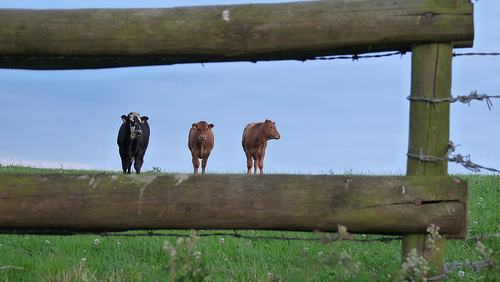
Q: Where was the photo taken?
A: It was taken at the field.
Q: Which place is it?
A: It is a field.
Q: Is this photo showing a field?
A: Yes, it is showing a field.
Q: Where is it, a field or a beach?
A: It is a field.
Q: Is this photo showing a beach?
A: No, the picture is showing a field.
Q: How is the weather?
A: It is clear.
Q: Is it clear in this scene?
A: Yes, it is clear.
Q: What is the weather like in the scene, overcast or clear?
A: It is clear.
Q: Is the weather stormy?
A: No, it is clear.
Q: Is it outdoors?
A: Yes, it is outdoors.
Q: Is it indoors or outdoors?
A: It is outdoors.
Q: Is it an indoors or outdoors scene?
A: It is outdoors.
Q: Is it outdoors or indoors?
A: It is outdoors.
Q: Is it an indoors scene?
A: No, it is outdoors.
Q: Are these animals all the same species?
A: Yes, all the animals are cows.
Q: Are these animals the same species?
A: Yes, all the animals are cows.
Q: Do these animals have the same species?
A: Yes, all the animals are cows.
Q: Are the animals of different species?
A: No, all the animals are cows.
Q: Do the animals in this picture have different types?
A: No, all the animals are cows.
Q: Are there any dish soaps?
A: No, there are no dish soaps.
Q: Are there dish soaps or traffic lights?
A: No, there are no dish soaps or traffic lights.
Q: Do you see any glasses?
A: No, there are no glasses.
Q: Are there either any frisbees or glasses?
A: No, there are no glasses or frisbees.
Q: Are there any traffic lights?
A: No, there are no traffic lights.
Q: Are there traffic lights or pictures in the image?
A: No, there are no traffic lights or pictures.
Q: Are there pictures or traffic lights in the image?
A: No, there are no traffic lights or pictures.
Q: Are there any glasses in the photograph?
A: No, there are no glasses.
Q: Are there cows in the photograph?
A: Yes, there is a cow.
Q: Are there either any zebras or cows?
A: Yes, there is a cow.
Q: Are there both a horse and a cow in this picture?
A: No, there is a cow but no horses.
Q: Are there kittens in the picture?
A: No, there are no kittens.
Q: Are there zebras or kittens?
A: No, there are no kittens or zebras.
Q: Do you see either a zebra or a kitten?
A: No, there are no kittens or zebras.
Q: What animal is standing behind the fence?
A: The cow is standing behind the fence.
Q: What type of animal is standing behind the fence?
A: The animal is a cow.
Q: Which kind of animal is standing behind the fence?
A: The animal is a cow.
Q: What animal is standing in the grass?
A: The cow is standing in the grass.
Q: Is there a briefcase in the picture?
A: No, there are no briefcases.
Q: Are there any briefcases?
A: No, there are no briefcases.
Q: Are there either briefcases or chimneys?
A: No, there are no briefcases or chimneys.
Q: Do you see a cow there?
A: Yes, there is a cow.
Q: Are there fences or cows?
A: Yes, there is a cow.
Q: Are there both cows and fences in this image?
A: Yes, there are both a cow and a fence.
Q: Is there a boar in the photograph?
A: No, there are no boars.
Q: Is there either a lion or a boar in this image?
A: No, there are no boars or lions.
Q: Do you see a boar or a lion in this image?
A: No, there are no boars or lions.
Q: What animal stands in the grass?
A: The animal is a cow.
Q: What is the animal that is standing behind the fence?
A: The animal is a cow.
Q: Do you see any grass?
A: Yes, there is grass.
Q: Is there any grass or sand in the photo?
A: Yes, there is grass.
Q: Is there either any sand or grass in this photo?
A: Yes, there is grass.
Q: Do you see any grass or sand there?
A: Yes, there is grass.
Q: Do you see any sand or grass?
A: Yes, there is grass.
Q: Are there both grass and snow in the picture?
A: No, there is grass but no snow.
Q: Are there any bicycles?
A: No, there are no bicycles.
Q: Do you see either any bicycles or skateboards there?
A: No, there are no bicycles or skateboards.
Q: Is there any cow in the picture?
A: Yes, there is a cow.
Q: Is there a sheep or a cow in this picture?
A: Yes, there is a cow.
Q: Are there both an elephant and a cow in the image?
A: No, there is a cow but no elephants.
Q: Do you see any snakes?
A: No, there are no snakes.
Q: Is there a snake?
A: No, there are no snakes.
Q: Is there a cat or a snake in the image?
A: No, there are no snakes or cats.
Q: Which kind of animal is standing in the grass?
A: The animal is a cow.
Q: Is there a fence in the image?
A: Yes, there is a fence.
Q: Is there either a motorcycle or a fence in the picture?
A: Yes, there is a fence.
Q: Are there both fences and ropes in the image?
A: No, there is a fence but no ropes.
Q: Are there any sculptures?
A: No, there are no sculptures.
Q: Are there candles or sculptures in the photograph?
A: No, there are no sculptures or candles.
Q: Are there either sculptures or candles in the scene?
A: No, there are no sculptures or candles.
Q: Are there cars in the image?
A: No, there are no cars.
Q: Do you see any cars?
A: No, there are no cars.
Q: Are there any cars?
A: No, there are no cars.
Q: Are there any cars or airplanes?
A: No, there are no cars or airplanes.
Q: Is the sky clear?
A: Yes, the sky is clear.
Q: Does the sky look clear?
A: Yes, the sky is clear.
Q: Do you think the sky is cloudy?
A: No, the sky is clear.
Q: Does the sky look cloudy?
A: No, the sky is clear.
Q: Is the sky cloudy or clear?
A: The sky is clear.